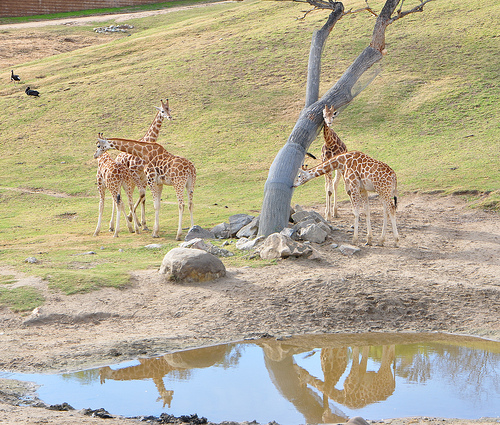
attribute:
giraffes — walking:
[294, 103, 364, 161]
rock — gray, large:
[158, 243, 230, 279]